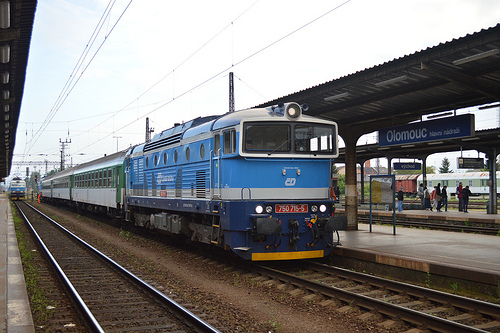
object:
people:
[417, 180, 474, 213]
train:
[34, 99, 347, 257]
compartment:
[123, 97, 336, 265]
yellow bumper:
[248, 246, 322, 263]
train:
[35, 99, 372, 266]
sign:
[367, 112, 477, 149]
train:
[28, 104, 345, 277]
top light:
[277, 98, 310, 124]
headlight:
[285, 101, 302, 120]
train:
[126, 101, 343, 269]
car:
[71, 143, 134, 220]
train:
[3, 173, 32, 198]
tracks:
[10, 199, 253, 331]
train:
[3, 173, 30, 204]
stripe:
[243, 240, 334, 262]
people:
[413, 175, 481, 211]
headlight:
[243, 202, 276, 216]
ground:
[36, 202, 376, 325]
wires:
[254, 213, 325, 250]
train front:
[232, 110, 337, 263]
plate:
[269, 192, 312, 217]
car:
[175, 112, 326, 243]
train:
[211, 114, 300, 221]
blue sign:
[367, 112, 476, 151]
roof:
[266, 30, 499, 139]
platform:
[330, 221, 497, 274]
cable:
[26, 0, 351, 168]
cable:
[49, 2, 259, 156]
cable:
[6, 2, 134, 182]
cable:
[4, 0, 119, 182]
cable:
[18, 2, 113, 169]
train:
[30, 71, 448, 287]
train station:
[264, 57, 497, 285]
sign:
[360, 103, 493, 166]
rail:
[297, 232, 471, 331]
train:
[35, 172, 150, 218]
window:
[291, 122, 339, 158]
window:
[241, 117, 293, 156]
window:
[185, 145, 192, 164]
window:
[198, 143, 208, 161]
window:
[142, 154, 152, 172]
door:
[211, 137, 219, 199]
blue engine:
[122, 101, 338, 265]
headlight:
[319, 204, 326, 213]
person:
[391, 187, 407, 216]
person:
[455, 181, 465, 212]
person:
[461, 179, 472, 212]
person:
[439, 183, 452, 212]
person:
[419, 186, 435, 215]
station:
[0, 0, 493, 330]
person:
[435, 181, 453, 216]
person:
[392, 183, 406, 215]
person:
[429, 181, 445, 216]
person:
[456, 179, 466, 210]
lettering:
[380, 123, 460, 140]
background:
[5, 158, 54, 227]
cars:
[41, 144, 135, 215]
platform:
[285, 188, 495, 298]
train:
[39, 99, 345, 271]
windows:
[243, 118, 338, 165]